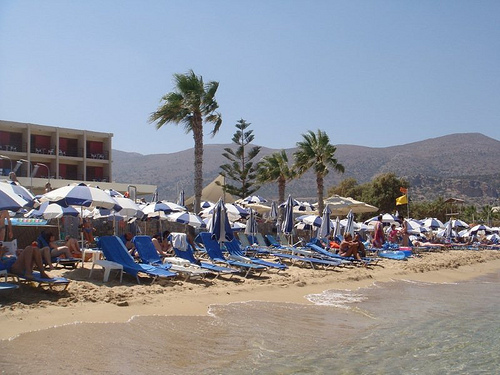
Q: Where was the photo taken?
A: It was taken at the beach.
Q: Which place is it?
A: It is a beach.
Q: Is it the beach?
A: Yes, it is the beach.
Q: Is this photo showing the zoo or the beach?
A: It is showing the beach.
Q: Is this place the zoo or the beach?
A: It is the beach.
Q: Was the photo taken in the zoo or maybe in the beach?
A: It was taken at the beach.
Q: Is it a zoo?
A: No, it is a beach.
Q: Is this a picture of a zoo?
A: No, the picture is showing a beach.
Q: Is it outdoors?
A: Yes, it is outdoors.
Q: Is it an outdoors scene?
A: Yes, it is outdoors.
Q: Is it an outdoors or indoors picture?
A: It is outdoors.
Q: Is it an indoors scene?
A: No, it is outdoors.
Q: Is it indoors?
A: No, it is outdoors.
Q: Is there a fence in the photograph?
A: No, there are no fences.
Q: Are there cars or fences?
A: No, there are no fences or cars.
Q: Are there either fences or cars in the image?
A: No, there are no fences or cars.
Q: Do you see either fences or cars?
A: No, there are no fences or cars.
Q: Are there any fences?
A: No, there are no fences.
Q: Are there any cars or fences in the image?
A: No, there are no fences or cars.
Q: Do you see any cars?
A: No, there are no cars.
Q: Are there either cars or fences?
A: No, there are no cars or fences.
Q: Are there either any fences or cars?
A: No, there are no fences or cars.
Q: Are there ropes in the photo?
A: No, there are no ropes.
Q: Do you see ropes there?
A: No, there are no ropes.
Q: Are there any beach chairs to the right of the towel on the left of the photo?
A: Yes, there is a beach chair to the right of the towel.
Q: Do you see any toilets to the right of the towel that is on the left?
A: No, there is a beach chair to the right of the towel.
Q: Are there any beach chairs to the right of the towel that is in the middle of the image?
A: Yes, there is a beach chair to the right of the towel.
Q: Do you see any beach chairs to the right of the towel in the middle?
A: Yes, there is a beach chair to the right of the towel.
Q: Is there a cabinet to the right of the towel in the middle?
A: No, there is a beach chair to the right of the towel.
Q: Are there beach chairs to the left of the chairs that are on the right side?
A: Yes, there is a beach chair to the left of the chairs.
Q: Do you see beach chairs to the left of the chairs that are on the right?
A: Yes, there is a beach chair to the left of the chairs.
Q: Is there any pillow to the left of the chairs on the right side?
A: No, there is a beach chair to the left of the chairs.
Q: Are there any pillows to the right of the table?
A: No, there is a beach chair to the right of the table.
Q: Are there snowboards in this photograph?
A: No, there are no snowboards.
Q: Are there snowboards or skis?
A: No, there are no snowboards or skis.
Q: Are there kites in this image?
A: No, there are no kites.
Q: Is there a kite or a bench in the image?
A: No, there are no kites or benches.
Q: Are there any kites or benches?
A: No, there are no kites or benches.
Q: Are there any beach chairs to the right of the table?
A: Yes, there is a beach chair to the right of the table.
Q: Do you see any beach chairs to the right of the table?
A: Yes, there is a beach chair to the right of the table.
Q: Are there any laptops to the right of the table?
A: No, there is a beach chair to the right of the table.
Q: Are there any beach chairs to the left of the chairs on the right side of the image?
A: Yes, there is a beach chair to the left of the chairs.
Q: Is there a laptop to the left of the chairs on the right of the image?
A: No, there is a beach chair to the left of the chairs.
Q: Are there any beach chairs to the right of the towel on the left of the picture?
A: Yes, there is a beach chair to the right of the towel.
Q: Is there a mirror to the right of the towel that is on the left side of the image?
A: No, there is a beach chair to the right of the towel.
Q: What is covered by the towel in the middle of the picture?
A: The beach chair is covered by the towel.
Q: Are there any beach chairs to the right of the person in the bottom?
A: Yes, there is a beach chair to the right of the person.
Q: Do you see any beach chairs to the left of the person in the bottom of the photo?
A: No, the beach chair is to the right of the person.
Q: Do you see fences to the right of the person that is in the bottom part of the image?
A: No, there is a beach chair to the right of the person.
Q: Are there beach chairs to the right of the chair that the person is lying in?
A: Yes, there is a beach chair to the right of the chair.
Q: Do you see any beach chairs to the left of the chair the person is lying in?
A: No, the beach chair is to the right of the chair.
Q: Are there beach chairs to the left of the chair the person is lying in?
A: No, the beach chair is to the right of the chair.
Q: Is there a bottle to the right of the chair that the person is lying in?
A: No, there is a beach chair to the right of the chair.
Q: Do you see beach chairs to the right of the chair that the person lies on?
A: Yes, there is a beach chair to the right of the chair.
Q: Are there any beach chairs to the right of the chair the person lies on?
A: Yes, there is a beach chair to the right of the chair.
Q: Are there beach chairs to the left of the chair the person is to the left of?
A: No, the beach chair is to the right of the chair.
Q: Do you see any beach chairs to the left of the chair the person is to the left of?
A: No, the beach chair is to the right of the chair.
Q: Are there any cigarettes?
A: No, there are no cigarettes.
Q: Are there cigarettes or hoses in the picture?
A: No, there are no cigarettes or hoses.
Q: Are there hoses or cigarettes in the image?
A: No, there are no cigarettes or hoses.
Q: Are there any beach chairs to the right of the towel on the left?
A: Yes, there is a beach chair to the right of the towel.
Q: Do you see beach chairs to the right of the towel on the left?
A: Yes, there is a beach chair to the right of the towel.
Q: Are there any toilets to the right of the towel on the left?
A: No, there is a beach chair to the right of the towel.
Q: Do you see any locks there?
A: No, there are no locks.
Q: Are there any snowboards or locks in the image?
A: No, there are no locks or snowboards.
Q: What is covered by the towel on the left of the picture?
A: The beach chair is covered by the towel.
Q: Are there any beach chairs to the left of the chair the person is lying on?
A: No, the beach chair is to the right of the chair.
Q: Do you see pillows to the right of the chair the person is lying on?
A: No, there is a beach chair to the right of the chair.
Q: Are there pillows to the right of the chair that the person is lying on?
A: No, there is a beach chair to the right of the chair.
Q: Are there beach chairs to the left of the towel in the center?
A: Yes, there is a beach chair to the left of the towel.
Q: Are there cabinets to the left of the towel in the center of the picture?
A: No, there is a beach chair to the left of the towel.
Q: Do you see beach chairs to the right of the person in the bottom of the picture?
A: Yes, there is a beach chair to the right of the person.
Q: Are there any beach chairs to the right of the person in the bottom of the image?
A: Yes, there is a beach chair to the right of the person.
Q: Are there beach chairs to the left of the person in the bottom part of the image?
A: No, the beach chair is to the right of the person.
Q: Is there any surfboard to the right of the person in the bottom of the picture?
A: No, there is a beach chair to the right of the person.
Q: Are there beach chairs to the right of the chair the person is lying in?
A: Yes, there is a beach chair to the right of the chair.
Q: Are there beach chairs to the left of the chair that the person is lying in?
A: No, the beach chair is to the right of the chair.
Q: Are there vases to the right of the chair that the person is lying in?
A: No, there is a beach chair to the right of the chair.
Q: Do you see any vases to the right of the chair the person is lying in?
A: No, there is a beach chair to the right of the chair.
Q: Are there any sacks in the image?
A: No, there are no sacks.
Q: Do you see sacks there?
A: No, there are no sacks.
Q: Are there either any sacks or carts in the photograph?
A: No, there are no sacks or carts.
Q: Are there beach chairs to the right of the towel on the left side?
A: Yes, there is a beach chair to the right of the towel.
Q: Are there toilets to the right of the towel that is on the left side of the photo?
A: No, there is a beach chair to the right of the towel.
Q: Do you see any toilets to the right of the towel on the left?
A: No, there is a beach chair to the right of the towel.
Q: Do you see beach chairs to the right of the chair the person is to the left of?
A: Yes, there is a beach chair to the right of the chair.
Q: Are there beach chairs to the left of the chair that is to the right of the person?
A: No, the beach chair is to the right of the chair.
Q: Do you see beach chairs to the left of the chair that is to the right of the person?
A: No, the beach chair is to the right of the chair.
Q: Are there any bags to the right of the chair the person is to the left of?
A: No, there is a beach chair to the right of the chair.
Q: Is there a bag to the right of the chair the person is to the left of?
A: No, there is a beach chair to the right of the chair.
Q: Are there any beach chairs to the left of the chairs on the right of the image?
A: Yes, there is a beach chair to the left of the chairs.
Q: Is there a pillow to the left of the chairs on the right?
A: No, there is a beach chair to the left of the chairs.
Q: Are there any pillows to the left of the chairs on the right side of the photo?
A: No, there is a beach chair to the left of the chairs.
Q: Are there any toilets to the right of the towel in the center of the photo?
A: No, there is a beach chair to the right of the towel.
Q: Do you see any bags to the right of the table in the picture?
A: No, there is a beach chair to the right of the table.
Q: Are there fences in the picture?
A: No, there are no fences.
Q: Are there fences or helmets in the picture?
A: No, there are no fences or helmets.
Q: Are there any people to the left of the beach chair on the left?
A: Yes, there is a person to the left of the beach chair.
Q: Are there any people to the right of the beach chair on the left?
A: No, the person is to the left of the beach chair.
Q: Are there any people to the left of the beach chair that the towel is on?
A: Yes, there is a person to the left of the beach chair.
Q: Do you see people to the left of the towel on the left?
A: Yes, there is a person to the left of the towel.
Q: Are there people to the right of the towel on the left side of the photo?
A: No, the person is to the left of the towel.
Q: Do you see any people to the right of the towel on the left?
A: No, the person is to the left of the towel.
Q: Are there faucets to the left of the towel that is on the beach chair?
A: No, there is a person to the left of the towel.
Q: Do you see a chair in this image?
A: Yes, there is a chair.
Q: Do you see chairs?
A: Yes, there is a chair.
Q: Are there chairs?
A: Yes, there is a chair.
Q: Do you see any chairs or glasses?
A: Yes, there is a chair.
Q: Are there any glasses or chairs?
A: Yes, there is a chair.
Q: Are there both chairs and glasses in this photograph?
A: No, there is a chair but no glasses.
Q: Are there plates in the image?
A: No, there are no plates.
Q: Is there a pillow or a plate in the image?
A: No, there are no plates or pillows.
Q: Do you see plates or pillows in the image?
A: No, there are no plates or pillows.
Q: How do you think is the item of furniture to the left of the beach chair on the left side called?
A: The piece of furniture is a chair.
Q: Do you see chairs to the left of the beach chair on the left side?
A: Yes, there is a chair to the left of the beach chair.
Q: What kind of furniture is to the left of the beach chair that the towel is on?
A: The piece of furniture is a chair.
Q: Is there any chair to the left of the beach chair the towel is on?
A: Yes, there is a chair to the left of the beach chair.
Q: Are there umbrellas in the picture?
A: Yes, there is an umbrella.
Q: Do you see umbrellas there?
A: Yes, there is an umbrella.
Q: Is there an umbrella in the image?
A: Yes, there is an umbrella.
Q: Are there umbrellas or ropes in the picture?
A: Yes, there is an umbrella.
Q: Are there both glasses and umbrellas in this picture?
A: No, there is an umbrella but no glasses.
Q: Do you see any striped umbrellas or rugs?
A: Yes, there is a striped umbrella.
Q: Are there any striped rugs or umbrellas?
A: Yes, there is a striped umbrella.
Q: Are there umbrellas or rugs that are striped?
A: Yes, the umbrella is striped.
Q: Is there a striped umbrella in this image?
A: Yes, there is a striped umbrella.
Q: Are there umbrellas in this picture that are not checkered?
A: Yes, there is a striped umbrella.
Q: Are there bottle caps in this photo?
A: No, there are no bottle caps.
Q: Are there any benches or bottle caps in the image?
A: No, there are no bottle caps or benches.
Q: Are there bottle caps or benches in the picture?
A: No, there are no bottle caps or benches.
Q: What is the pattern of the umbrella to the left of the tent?
A: The umbrella is striped.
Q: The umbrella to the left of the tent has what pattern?
A: The umbrella is striped.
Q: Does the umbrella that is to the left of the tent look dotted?
A: No, the umbrella is striped.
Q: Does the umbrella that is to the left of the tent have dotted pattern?
A: No, the umbrella is striped.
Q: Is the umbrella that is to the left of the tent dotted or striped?
A: The umbrella is striped.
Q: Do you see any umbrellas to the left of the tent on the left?
A: Yes, there is an umbrella to the left of the tent.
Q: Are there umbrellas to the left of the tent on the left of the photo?
A: Yes, there is an umbrella to the left of the tent.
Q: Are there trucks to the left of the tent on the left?
A: No, there is an umbrella to the left of the tent.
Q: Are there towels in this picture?
A: Yes, there is a towel.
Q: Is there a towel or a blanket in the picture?
A: Yes, there is a towel.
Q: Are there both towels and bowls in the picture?
A: No, there is a towel but no bowls.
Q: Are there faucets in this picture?
A: No, there are no faucets.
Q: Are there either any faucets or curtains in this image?
A: No, there are no faucets or curtains.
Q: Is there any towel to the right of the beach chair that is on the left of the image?
A: Yes, there is a towel to the right of the beach chair.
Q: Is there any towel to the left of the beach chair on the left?
A: No, the towel is to the right of the beach chair.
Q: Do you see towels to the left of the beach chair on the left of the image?
A: No, the towel is to the right of the beach chair.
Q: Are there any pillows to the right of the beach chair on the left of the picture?
A: No, there is a towel to the right of the beach chair.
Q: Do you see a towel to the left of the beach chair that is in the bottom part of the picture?
A: Yes, there is a towel to the left of the beach chair.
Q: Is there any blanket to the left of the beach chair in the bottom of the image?
A: No, there is a towel to the left of the beach chair.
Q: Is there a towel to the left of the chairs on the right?
A: Yes, there is a towel to the left of the chairs.